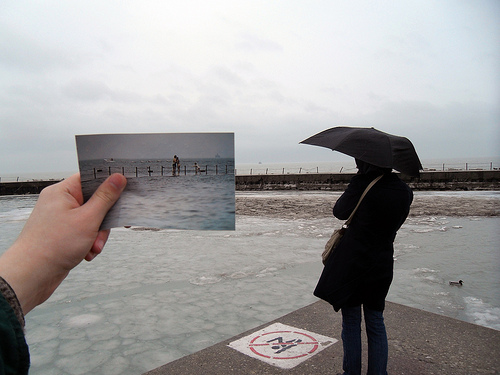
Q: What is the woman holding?
A: An umbrella.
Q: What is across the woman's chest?
A: A purse.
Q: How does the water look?
A: It looks murky.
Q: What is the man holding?
A: A picture.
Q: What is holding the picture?
A: A hand.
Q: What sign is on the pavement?
A: No swimming.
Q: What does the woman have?
A: An umbrella.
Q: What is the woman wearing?
A: Jeans.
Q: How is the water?
A: Calm.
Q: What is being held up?
A: Photo.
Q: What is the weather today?
A: Cloudy.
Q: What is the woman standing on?
A: Pier.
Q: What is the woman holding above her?
A: Umbrella.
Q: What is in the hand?
A: Photograph.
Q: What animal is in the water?
A: Duck.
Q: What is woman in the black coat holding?
A: Umbrella.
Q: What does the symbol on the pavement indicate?
A: No Swimming.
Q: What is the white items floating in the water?
A: Ice.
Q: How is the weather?
A: Cloudy.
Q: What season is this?
A: Winter.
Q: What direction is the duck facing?
A: Right.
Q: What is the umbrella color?
A: Black.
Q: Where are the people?
A: Near a lake.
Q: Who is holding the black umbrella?
A: A woman carrying a purse.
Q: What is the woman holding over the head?
A: Black umbrella.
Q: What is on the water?
A: Ice.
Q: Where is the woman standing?
A: On a pier.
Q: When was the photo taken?
A: Daytime.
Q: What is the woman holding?
A: An umbrella.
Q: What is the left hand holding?
A: A picture.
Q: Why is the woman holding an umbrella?
A: It is raining.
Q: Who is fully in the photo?
A: A woman.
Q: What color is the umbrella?
A: Black.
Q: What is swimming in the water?
A: A duck.